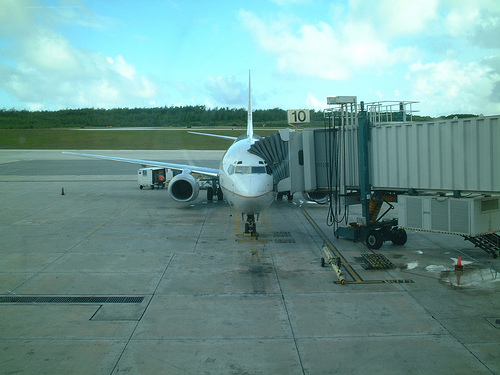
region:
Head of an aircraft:
[216, 147, 283, 247]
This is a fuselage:
[166, 155, 206, 222]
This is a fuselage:
[298, 185, 340, 212]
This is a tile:
[125, 292, 295, 340]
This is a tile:
[286, 281, 455, 344]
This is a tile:
[84, 213, 216, 258]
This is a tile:
[14, 284, 168, 351]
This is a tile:
[127, 338, 301, 373]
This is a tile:
[57, 168, 162, 248]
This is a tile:
[277, 244, 382, 295]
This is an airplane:
[216, 132, 283, 224]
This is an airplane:
[199, 120, 295, 260]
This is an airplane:
[91, 105, 342, 287]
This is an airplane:
[61, 35, 389, 322]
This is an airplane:
[144, 136, 419, 303]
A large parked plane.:
[61, 69, 291, 237]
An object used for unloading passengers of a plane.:
[251, 95, 497, 254]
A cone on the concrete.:
[57, 183, 71, 199]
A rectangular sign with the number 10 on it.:
[283, 108, 314, 125]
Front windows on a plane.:
[233, 162, 269, 176]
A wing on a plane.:
[57, 142, 222, 182]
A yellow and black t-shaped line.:
[298, 197, 390, 289]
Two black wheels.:
[364, 227, 409, 247]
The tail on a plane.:
[245, 68, 257, 133]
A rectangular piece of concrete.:
[127, 293, 296, 343]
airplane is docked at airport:
[60, 68, 292, 237]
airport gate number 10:
[283, 108, 312, 125]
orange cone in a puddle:
[423, 253, 498, 295]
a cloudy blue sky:
[0, 0, 499, 112]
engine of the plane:
[166, 173, 200, 205]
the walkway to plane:
[248, 110, 498, 200]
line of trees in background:
[1, 104, 287, 127]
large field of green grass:
[1, 127, 243, 151]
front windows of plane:
[226, 163, 273, 177]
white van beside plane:
[135, 163, 175, 191]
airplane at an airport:
[41, 63, 297, 259]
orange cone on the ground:
[444, 238, 470, 279]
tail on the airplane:
[237, 67, 267, 137]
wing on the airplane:
[52, 123, 220, 192]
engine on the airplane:
[162, 160, 203, 215]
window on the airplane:
[227, 157, 269, 174]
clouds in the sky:
[25, 19, 115, 91]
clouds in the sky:
[387, 12, 475, 97]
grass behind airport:
[36, 128, 163, 145]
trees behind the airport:
[18, 103, 220, 130]